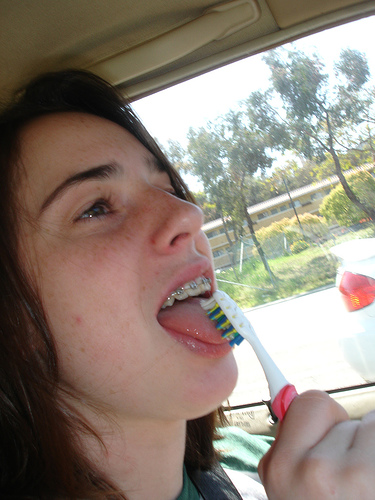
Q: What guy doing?
A: Brushing teeth.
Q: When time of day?
A: Daytime.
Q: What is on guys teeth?
A: Braces.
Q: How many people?
A: One.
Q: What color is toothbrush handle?
A: Pink.